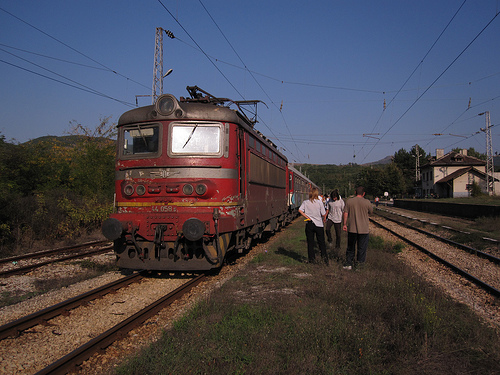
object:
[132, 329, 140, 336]
gravel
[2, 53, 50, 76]
wires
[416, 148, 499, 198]
building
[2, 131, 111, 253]
hill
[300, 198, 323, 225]
shirt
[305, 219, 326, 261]
pants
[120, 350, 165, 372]
grass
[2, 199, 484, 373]
field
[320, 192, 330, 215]
person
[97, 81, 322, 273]
train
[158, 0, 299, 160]
wire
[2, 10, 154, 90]
wire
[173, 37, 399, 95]
wire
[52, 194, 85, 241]
plant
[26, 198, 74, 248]
plant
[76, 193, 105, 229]
plant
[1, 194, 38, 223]
plant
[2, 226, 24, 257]
plant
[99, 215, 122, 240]
bumper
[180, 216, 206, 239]
bumper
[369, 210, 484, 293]
rail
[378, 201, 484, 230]
road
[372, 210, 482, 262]
rail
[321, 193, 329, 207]
person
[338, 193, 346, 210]
person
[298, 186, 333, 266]
person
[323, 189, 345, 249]
person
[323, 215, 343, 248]
pants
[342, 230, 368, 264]
pants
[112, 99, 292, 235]
train engine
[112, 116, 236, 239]
surface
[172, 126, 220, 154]
windshield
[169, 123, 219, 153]
light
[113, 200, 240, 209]
stripe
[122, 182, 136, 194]
light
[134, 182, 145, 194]
light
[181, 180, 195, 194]
light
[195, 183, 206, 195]
light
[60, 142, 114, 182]
grass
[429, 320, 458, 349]
grass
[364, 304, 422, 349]
foliage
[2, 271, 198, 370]
tracks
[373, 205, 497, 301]
tracks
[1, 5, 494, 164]
sky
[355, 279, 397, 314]
grass patch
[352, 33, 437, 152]
wires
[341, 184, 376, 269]
man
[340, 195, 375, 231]
shirt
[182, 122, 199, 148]
windshield wipers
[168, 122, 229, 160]
window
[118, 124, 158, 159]
window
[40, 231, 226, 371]
rails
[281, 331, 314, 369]
foliage